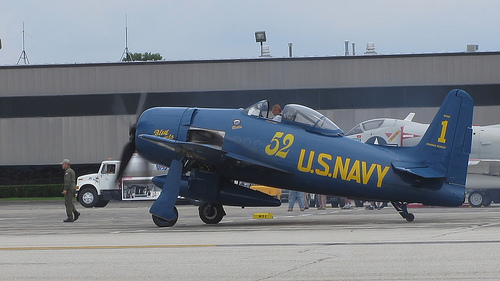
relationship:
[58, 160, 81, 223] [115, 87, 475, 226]
man walking away from aircraft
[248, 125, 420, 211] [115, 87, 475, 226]
writing on aircraft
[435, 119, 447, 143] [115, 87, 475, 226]
writing on aircraft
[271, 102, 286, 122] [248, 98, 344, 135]
man sitting in cockpit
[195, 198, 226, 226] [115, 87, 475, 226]
front wheel of aircraft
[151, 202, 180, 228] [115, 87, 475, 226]
front wheel of aircraft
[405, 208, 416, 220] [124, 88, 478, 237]
wheel of plane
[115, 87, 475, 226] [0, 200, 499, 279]
aircraft on runway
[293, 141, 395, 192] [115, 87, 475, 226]
letters on aircraft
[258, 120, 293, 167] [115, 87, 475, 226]
number on aircraft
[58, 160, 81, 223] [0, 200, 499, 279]
man walking on runway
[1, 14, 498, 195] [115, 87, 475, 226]
airport behind aircraft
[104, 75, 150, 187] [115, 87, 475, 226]
propeller on front of aircraft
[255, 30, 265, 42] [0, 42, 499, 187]
flag light on top of building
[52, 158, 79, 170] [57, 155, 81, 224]
cap of man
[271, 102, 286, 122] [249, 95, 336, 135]
man in cockpit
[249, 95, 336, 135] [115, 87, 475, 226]
cockpit of aircraft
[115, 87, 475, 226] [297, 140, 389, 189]
aircraft with signage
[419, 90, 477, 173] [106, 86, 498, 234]
tail of airplane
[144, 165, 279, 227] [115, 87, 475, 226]
landing gear of aircraft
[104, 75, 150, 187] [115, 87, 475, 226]
propeller on a aircraft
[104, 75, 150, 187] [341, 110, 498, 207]
propeller on a plane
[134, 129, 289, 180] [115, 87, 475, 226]
wing of an aircraft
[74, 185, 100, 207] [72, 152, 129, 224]
wheel of a vehicle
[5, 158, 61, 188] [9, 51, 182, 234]
windows on a building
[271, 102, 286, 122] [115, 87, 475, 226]
man of on aircraft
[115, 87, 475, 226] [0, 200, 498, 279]
aircraft on airstrip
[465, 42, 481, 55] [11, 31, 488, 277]
light on top of airport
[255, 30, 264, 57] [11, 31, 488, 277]
flag light on top of airport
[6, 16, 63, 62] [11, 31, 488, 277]
antenna on top of airport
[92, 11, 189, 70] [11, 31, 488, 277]
antenna on top of airport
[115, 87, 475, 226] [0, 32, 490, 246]
aircraft in airport